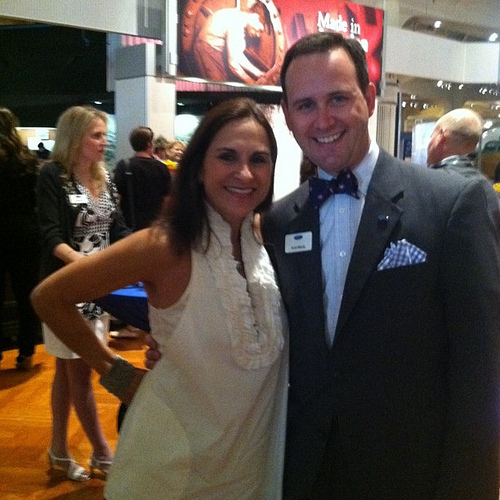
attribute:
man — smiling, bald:
[267, 29, 496, 499]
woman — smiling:
[27, 83, 296, 497]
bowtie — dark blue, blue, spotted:
[296, 168, 364, 202]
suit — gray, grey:
[258, 168, 498, 500]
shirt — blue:
[309, 133, 389, 347]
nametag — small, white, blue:
[281, 232, 318, 258]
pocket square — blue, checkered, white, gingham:
[371, 236, 434, 275]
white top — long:
[105, 203, 298, 500]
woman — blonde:
[19, 104, 131, 485]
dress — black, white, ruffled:
[32, 158, 128, 360]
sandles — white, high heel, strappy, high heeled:
[35, 445, 124, 485]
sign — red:
[148, 3, 400, 97]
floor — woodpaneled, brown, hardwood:
[0, 292, 150, 500]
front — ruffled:
[191, 209, 291, 470]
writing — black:
[280, 241, 318, 253]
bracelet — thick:
[87, 353, 143, 398]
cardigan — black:
[26, 159, 141, 293]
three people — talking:
[120, 120, 187, 165]